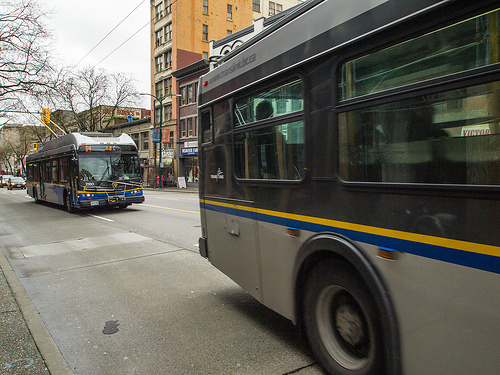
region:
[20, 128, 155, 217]
Bus on the street.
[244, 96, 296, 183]
person on the bus.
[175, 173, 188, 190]
White sign on the street.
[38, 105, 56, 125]
Stop light above the street.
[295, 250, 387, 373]
Black tire on the bus.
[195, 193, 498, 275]
blue and yellow stripe on the bus.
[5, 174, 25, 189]
Car on the road.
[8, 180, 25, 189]
head lights on the car.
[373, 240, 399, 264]
reflector light on the side of the bus.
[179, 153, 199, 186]
store front in the background.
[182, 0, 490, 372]
grey bus on road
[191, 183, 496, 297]
blue and yellow stripe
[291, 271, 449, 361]
bus has grey tire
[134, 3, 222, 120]
brown and tall building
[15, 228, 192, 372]
road is dark grey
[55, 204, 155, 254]
white line on road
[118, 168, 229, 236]
yellow line on road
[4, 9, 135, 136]
bare trees behind bus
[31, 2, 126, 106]
sky is grey and cloudy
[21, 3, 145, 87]
thick clouds in sky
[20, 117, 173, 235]
This is a bus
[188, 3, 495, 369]
This is a bus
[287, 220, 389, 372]
Wheel of a bus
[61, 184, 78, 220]
Wheel of a bus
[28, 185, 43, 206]
Wheel of a bus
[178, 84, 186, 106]
This is a window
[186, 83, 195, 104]
This is a window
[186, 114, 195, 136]
This is a window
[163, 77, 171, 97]
This is a window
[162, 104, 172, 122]
This is a window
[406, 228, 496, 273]
blue and yellow striped on the bus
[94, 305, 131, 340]
a black oil spot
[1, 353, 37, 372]
a number spray painted in blue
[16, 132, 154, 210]
a city bus on the street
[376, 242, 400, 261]
yellow reflector light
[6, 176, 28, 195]
a black car following the bus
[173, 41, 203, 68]
a burgundy square on a building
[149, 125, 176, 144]
blue and orange signs on a pole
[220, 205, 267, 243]
the cover over a gas tank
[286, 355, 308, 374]
a crack in the street